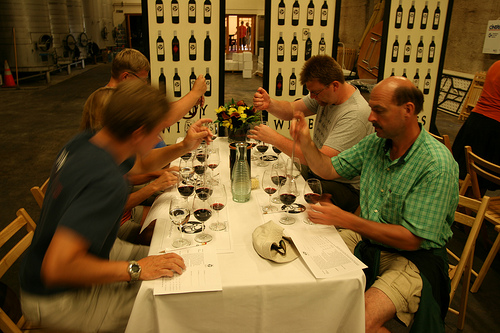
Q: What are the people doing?
A: Wine tasting.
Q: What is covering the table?
A: White tablecloth.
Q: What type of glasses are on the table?
A: Wine glasses.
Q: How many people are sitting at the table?
A: 5.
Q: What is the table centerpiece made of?
A: Flowers.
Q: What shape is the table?
A: Rectangle.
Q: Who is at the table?
A: Some people.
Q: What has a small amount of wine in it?
A: Each glass.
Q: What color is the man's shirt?
A: Green.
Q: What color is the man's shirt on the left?
A: Black.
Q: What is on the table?
A: Drinks.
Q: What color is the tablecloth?
A: White.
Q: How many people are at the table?
A: Five.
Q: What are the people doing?
A: Talking.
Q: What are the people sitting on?
A: Chairs.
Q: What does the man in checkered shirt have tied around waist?
A: Sweater.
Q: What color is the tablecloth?
A: White.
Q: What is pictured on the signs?
A: Varieties of wine.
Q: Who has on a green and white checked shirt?
A: A balding man with a green sweater tied around his waist.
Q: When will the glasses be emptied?
A: When the tasters finish them, or decide to taste something else.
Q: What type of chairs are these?
A: Folding chairs.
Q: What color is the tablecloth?
A: White..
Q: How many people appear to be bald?
A: Just one.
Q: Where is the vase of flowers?
A: In the center of the table.